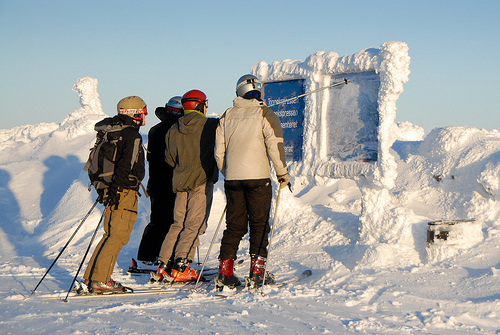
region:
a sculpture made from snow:
[69, 74, 111, 131]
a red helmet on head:
[183, 92, 213, 114]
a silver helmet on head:
[231, 78, 261, 96]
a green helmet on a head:
[117, 88, 143, 113]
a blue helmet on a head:
[164, 95, 181, 116]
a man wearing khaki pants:
[91, 96, 138, 296]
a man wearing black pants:
[206, 71, 288, 293]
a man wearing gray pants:
[161, 90, 213, 277]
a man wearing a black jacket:
[145, 106, 170, 283]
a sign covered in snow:
[264, 65, 396, 179]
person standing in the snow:
[195, 73, 291, 300]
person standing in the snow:
[143, 85, 233, 293]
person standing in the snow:
[125, 91, 190, 276]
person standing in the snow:
[55, 95, 175, 302]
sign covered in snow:
[240, 40, 412, 187]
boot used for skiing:
[242, 257, 277, 291]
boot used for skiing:
[210, 254, 247, 293]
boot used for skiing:
[167, 253, 203, 287]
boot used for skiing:
[151, 255, 176, 286]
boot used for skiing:
[88, 273, 125, 293]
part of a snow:
[305, 268, 338, 308]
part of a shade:
[336, 200, 377, 237]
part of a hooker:
[250, 255, 278, 295]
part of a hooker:
[256, 245, 283, 290]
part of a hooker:
[240, 221, 282, 306]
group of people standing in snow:
[0, 37, 422, 307]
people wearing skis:
[5, 0, 312, 321]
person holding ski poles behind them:
[8, 82, 150, 303]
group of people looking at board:
[25, 34, 472, 321]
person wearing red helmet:
[172, 82, 210, 112]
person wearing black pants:
[211, 169, 286, 261]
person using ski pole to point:
[153, 79, 370, 299]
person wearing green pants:
[77, 178, 139, 284]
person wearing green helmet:
[108, 90, 157, 126]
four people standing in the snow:
[0, 75, 498, 333]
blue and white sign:
[267, 82, 305, 161]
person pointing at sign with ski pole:
[155, 68, 382, 288]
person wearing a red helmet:
[155, 85, 217, 290]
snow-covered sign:
[321, 56, 386, 171]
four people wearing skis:
[35, 75, 305, 300]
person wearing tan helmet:
[82, 95, 144, 295]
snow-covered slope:
[0, 121, 495, 327]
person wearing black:
[142, 95, 182, 257]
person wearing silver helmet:
[216, 73, 286, 288]